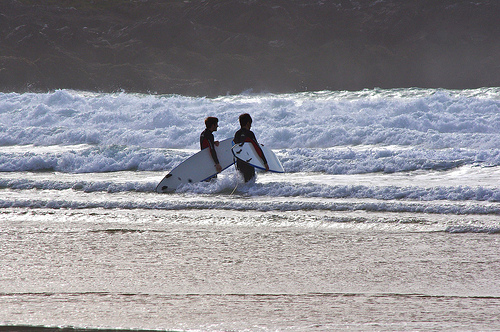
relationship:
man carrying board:
[199, 117, 223, 182] [230, 143, 286, 174]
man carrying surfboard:
[199, 117, 223, 182] [152, 132, 239, 194]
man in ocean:
[199, 117, 223, 182] [0, 0, 497, 327]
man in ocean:
[229, 107, 270, 184] [0, 0, 497, 327]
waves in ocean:
[1, 87, 498, 173] [1, 83, 498, 234]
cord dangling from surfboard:
[223, 165, 275, 207] [236, 140, 287, 175]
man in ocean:
[199, 117, 223, 182] [379, 96, 455, 200]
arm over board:
[248, 130, 270, 171] [230, 143, 285, 171]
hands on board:
[208, 130, 231, 183] [159, 132, 244, 192]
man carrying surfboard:
[199, 117, 223, 182] [153, 135, 238, 190]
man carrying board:
[230, 113, 269, 184] [230, 143, 286, 174]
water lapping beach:
[5, 224, 498, 329] [0, 221, 500, 330]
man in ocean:
[230, 113, 269, 184] [0, 86, 500, 330]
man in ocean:
[199, 117, 223, 182] [0, 86, 500, 330]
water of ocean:
[5, 224, 498, 329] [1, 83, 498, 234]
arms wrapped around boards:
[205, 135, 231, 177] [166, 116, 285, 203]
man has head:
[230, 113, 269, 184] [238, 114, 253, 128]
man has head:
[199, 117, 223, 182] [206, 118, 220, 128]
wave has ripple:
[57, 142, 125, 172] [9, 169, 19, 172]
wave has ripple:
[57, 142, 125, 172] [79, 167, 94, 182]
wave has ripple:
[3, 140, 85, 167] [79, 164, 90, 174]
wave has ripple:
[3, 140, 85, 167] [44, 171, 64, 181]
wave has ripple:
[3, 140, 85, 167] [5, 157, 25, 167]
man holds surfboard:
[230, 113, 269, 184] [145, 153, 167, 192]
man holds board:
[199, 117, 223, 182] [154, 136, 245, 194]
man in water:
[199, 117, 223, 182] [0, 87, 497, 325]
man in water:
[230, 113, 269, 184] [0, 87, 497, 325]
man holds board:
[199, 117, 223, 182] [230, 143, 286, 174]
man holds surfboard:
[230, 113, 269, 184] [153, 135, 238, 190]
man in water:
[199, 117, 223, 182] [2, 88, 498, 215]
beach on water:
[0, 221, 500, 330] [0, 87, 497, 325]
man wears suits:
[193, 113, 226, 186] [235, 128, 253, 170]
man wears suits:
[230, 113, 269, 184] [198, 128, 220, 169]